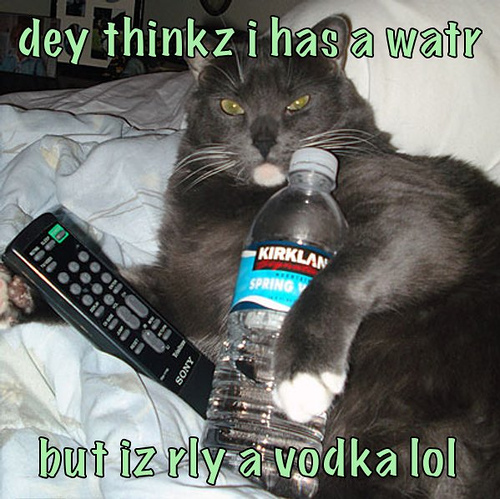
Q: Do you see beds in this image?
A: Yes, there is a bed.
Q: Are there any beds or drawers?
A: Yes, there is a bed.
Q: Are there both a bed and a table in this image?
A: No, there is a bed but no tables.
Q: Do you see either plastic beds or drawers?
A: Yes, there is a plastic bed.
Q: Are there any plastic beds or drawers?
A: Yes, there is a plastic bed.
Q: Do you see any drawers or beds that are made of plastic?
A: Yes, the bed is made of plastic.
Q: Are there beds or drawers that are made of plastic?
A: Yes, the bed is made of plastic.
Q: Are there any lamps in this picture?
A: No, there are no lamps.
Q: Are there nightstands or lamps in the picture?
A: No, there are no lamps or nightstands.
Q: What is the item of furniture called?
A: The piece of furniture is a bed.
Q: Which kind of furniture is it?
A: The piece of furniture is a bed.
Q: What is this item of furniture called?
A: This is a bed.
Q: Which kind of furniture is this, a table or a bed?
A: This is a bed.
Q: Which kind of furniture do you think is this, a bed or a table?
A: This is a bed.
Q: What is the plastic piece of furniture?
A: The piece of furniture is a bed.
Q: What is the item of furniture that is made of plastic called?
A: The piece of furniture is a bed.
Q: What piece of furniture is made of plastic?
A: The piece of furniture is a bed.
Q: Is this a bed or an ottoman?
A: This is a bed.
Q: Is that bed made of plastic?
A: Yes, the bed is made of plastic.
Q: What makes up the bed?
A: The bed is made of plastic.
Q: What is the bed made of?
A: The bed is made of plastic.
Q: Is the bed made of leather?
A: No, the bed is made of plastic.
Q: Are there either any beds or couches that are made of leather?
A: No, there is a bed but it is made of plastic.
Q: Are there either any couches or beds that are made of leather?
A: No, there is a bed but it is made of plastic.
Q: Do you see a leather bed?
A: No, there is a bed but it is made of plastic.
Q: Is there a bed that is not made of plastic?
A: No, there is a bed but it is made of plastic.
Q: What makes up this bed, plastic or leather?
A: The bed is made of plastic.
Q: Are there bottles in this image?
A: Yes, there is a bottle.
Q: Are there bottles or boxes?
A: Yes, there is a bottle.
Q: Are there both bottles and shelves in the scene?
A: No, there is a bottle but no shelves.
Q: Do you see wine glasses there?
A: No, there are no wine glasses.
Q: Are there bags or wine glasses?
A: No, there are no wine glasses or bags.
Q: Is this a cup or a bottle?
A: This is a bottle.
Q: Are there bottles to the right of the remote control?
A: Yes, there is a bottle to the right of the remote control.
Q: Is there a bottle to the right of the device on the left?
A: Yes, there is a bottle to the right of the remote control.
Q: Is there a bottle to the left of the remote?
A: No, the bottle is to the right of the remote.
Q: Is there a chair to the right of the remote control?
A: No, there is a bottle to the right of the remote control.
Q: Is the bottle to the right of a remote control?
A: Yes, the bottle is to the right of a remote control.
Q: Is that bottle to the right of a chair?
A: No, the bottle is to the right of a remote control.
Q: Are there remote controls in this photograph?
A: Yes, there is a remote control.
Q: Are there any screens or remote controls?
A: Yes, there is a remote control.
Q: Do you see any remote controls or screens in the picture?
A: Yes, there is a remote control.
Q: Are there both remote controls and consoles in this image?
A: No, there is a remote control but no consoles.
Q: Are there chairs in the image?
A: No, there are no chairs.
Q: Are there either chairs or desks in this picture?
A: No, there are no chairs or desks.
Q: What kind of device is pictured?
A: The device is a remote control.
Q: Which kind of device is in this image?
A: The device is a remote control.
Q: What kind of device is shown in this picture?
A: The device is a remote control.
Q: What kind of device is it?
A: The device is a remote control.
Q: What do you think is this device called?
A: This is a remote control.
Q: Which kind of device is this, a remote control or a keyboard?
A: This is a remote control.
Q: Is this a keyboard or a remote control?
A: This is a remote control.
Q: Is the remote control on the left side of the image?
A: Yes, the remote control is on the left of the image.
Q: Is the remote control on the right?
A: No, the remote control is on the left of the image.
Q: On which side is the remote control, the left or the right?
A: The remote control is on the left of the image.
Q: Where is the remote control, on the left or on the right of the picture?
A: The remote control is on the left of the image.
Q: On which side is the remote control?
A: The remote control is on the left of the image.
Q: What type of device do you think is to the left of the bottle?
A: The device is a remote control.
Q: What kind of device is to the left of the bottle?
A: The device is a remote control.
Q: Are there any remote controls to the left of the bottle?
A: Yes, there is a remote control to the left of the bottle.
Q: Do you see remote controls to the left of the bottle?
A: Yes, there is a remote control to the left of the bottle.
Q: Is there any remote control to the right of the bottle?
A: No, the remote control is to the left of the bottle.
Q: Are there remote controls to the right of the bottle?
A: No, the remote control is to the left of the bottle.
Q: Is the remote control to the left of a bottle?
A: Yes, the remote control is to the left of a bottle.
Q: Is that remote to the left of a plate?
A: No, the remote is to the left of a bottle.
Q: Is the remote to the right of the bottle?
A: No, the remote is to the left of the bottle.